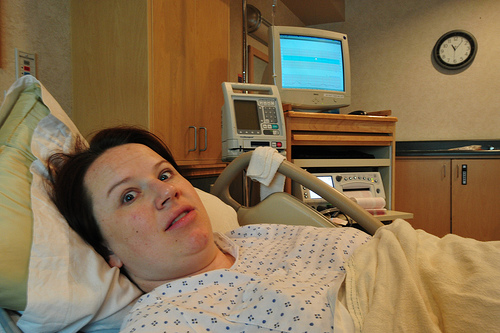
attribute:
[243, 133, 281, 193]
cloth — white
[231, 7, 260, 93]
rail — up